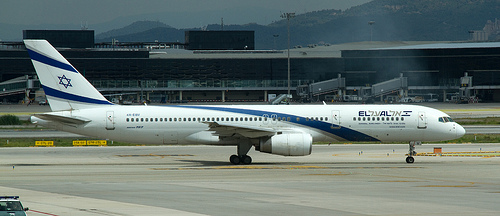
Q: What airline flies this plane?
A: El Al.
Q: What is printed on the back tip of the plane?
A: Israeli flag.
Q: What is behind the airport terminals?
A: View of mountains.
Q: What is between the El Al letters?
A: Hebrew letters.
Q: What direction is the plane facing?
A: Right.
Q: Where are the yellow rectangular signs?
A: On the runway curb.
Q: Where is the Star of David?
A: On the back tip of plane.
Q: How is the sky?
A: Cloudy, gray, and misty.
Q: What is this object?
A: Plane.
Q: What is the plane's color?
A: White.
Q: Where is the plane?
A: Tarmac.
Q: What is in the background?
A: Mountains.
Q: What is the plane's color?
A: White and blue.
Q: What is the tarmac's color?
A: Gray.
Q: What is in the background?
A: Terminal.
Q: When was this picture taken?
A: During the day.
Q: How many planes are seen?
A: 1.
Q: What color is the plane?
A: White with blue.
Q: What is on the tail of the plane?
A: An emblem.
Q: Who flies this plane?
A: A pilot.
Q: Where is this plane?
A: Airport.